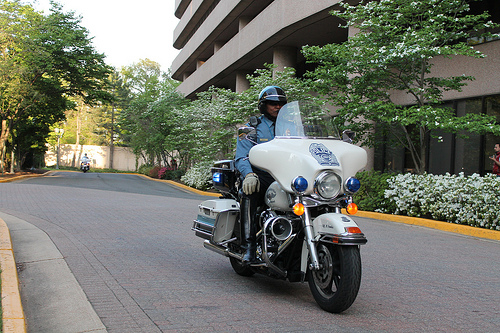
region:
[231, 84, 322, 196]
A police escort rider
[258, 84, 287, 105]
A black protective helmet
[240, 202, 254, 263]
Black and high leather boots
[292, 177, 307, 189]
A blue side light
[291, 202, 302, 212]
An orange side light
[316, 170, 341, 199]
The front center light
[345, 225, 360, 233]
A red reflector light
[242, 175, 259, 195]
A hand in a glove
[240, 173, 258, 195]
A hand on the knee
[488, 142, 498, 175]
A person behind a hedge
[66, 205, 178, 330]
The street is made of concrete bricks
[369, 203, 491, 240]
The sidewalk strip is yellow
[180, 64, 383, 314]
A police officer riding a motorcycle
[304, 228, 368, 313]
The front tire of the motorcycle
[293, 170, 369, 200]
The head lights of the motorcycle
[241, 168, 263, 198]
The officer has on gloves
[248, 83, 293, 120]
The helmet is on the office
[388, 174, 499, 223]
A bush of flowers on the side of road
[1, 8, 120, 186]
The tall tree with green leaves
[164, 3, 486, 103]
The building is the color gray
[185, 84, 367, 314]
police officer on patrol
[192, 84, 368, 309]
police officer headed downhill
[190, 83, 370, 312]
police officer steering with less than two hands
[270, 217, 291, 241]
speaker for the motorcycle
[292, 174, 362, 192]
blue lights on the front of the cycle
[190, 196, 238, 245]
cargo space on the cycle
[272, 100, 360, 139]
windshield of the cycle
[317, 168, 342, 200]
headlight on the cycle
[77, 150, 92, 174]
person in the distance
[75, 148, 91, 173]
cyclist in the background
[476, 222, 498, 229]
part of a road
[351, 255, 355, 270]
part of a wheel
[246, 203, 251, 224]
part of a boot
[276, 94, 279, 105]
part of an helmet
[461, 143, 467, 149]
part of a window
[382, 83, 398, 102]
part of a plant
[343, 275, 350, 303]
edge of a wheel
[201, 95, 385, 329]
This is a police officer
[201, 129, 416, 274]
This is a motorcycle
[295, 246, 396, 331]
These are wheels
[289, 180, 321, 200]
This is a blue light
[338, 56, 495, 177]
These are old trees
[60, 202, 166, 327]
This is pavement and black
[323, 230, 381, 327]
These are tires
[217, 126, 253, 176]
The uniform is blue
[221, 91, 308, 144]
This is a helmet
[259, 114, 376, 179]
The motorcycle is white